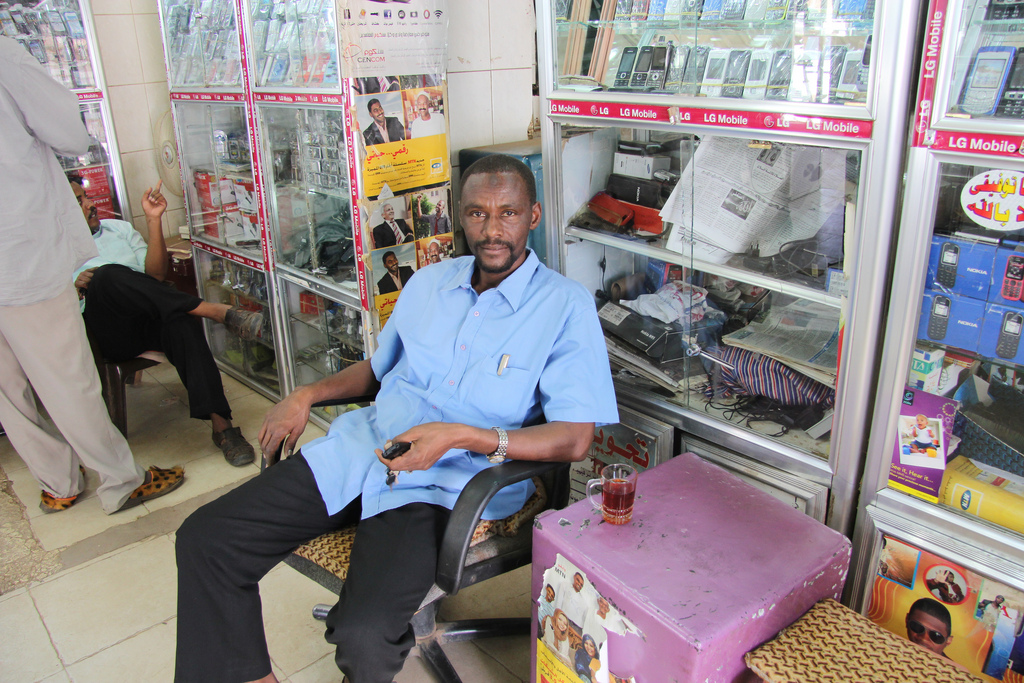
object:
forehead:
[460, 172, 534, 206]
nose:
[480, 212, 504, 237]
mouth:
[480, 245, 508, 256]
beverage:
[600, 478, 636, 524]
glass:
[586, 464, 638, 525]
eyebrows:
[463, 203, 485, 212]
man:
[172, 154, 619, 681]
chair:
[276, 382, 564, 602]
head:
[457, 154, 542, 274]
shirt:
[0, 37, 106, 305]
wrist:
[410, 420, 596, 462]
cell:
[381, 441, 413, 460]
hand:
[375, 422, 458, 473]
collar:
[443, 246, 542, 314]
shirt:
[293, 251, 622, 521]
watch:
[485, 426, 510, 464]